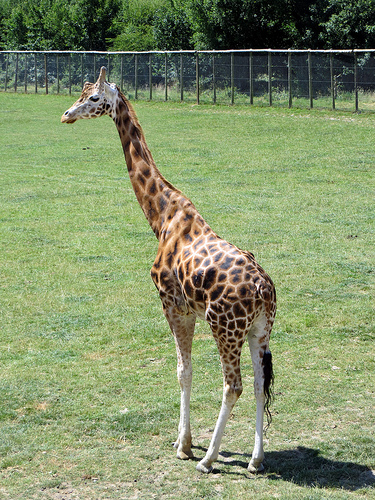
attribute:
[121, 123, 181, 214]
neck — extended, long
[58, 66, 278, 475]
giraffe — brown, white, standing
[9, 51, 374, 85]
fence — metal, wire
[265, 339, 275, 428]
tail — black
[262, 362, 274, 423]
hair — black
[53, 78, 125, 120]
head — white, brown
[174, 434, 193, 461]
foot — white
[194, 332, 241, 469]
leg — hind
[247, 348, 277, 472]
leg — hind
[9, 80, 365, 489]
area — green, grassy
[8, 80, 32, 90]
wheel — white, black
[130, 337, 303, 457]
legs — long, white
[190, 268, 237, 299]
patches — brown, white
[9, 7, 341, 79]
trees — back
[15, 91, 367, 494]
pasture — grass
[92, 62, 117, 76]
horns — small, furry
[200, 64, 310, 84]
posts — wood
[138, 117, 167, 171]
mane — brown, hair